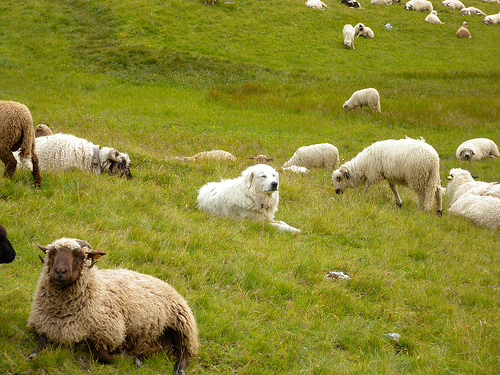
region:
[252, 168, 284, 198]
a working dog's serious expression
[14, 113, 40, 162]
a double-long sheeptail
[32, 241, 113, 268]
rusty ears on the perpendicular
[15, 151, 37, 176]
double-long sheeptail is brown until the cream colour tip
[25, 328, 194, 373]
little almost black legs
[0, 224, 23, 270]
only slightly visible dark examining sheep face, interacting with a goofy sheep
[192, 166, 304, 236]
white dog laying in the pasture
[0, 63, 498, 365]
herd of sheep in the foreground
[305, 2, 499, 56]
herd of sheep in the background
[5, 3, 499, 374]
grass pasture sheep are in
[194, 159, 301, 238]
dog laying among the sheep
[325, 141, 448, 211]
sheep grazing from the grass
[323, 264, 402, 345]
rocks in the grass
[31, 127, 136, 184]
sheep with black face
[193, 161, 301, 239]
white dog with his eyes closed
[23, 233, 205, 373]
sheep with brown face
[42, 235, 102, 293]
head of a sheep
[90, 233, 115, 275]
ear of a sheep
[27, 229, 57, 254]
ear of a sheep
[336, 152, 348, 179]
ear of a sheep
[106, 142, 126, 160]
ear of a sheep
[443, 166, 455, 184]
ear of a sheep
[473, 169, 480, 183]
ear of a sheep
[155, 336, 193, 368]
leg of a sheep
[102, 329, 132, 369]
leg of a sheep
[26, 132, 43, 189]
leg of a sheep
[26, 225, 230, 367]
gray sheep in green field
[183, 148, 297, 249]
white dog in green field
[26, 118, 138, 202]
gray sheep in green field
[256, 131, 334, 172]
gray sheep in green field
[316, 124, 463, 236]
gray sheep in green field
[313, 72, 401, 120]
gray sheep in green field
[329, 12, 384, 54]
gray sheep in green field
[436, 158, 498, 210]
gray sheep in green field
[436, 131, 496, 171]
gray sheep in green field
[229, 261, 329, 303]
short green and brown grass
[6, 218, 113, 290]
head of a sheep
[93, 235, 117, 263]
ear of a sheep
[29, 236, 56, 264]
ear of a sheep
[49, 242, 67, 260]
eye of a sheep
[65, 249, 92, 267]
eye of a sheep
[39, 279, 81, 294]
mouth of a sheep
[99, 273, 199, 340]
body of a sheep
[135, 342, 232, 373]
leg of a sheep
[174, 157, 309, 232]
An animal in a field.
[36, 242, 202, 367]
An animal in a field.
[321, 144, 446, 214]
An animal in a field.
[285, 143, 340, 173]
An animal in a field.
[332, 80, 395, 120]
An animal in a field.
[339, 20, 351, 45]
An animal in a field.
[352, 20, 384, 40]
An animal in a field.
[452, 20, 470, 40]
An animal in a field.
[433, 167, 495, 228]
An animal in a field.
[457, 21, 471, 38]
An animal in a field.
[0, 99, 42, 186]
Brown back end of a sheep.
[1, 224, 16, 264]
Black face of a sheep.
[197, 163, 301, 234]
White dog with black nose.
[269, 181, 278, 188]
Black nose on a dog.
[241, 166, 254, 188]
A dogs white right ear.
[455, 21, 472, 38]
Brownest sheep up on a hill.